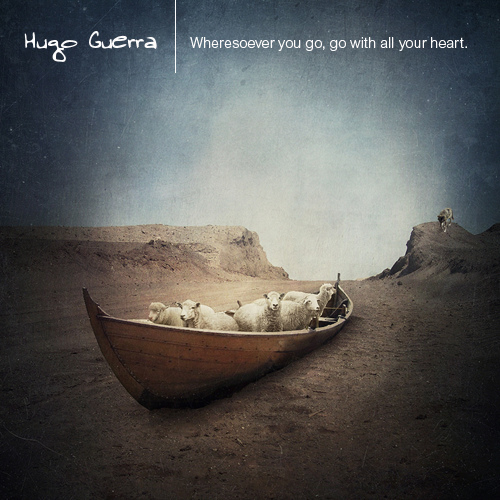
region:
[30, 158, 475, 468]
sheep contained inside boat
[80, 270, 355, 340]
curved edge of side of boat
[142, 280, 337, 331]
white sheep looking in different directions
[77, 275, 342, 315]
open far side of boat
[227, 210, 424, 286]
large opening between rocky partition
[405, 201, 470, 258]
predatory animal on flat circle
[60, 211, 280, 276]
dark and light grey ridges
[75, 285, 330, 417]
horizontal lines on boat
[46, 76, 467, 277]
muted grey and blue sky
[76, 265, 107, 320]
triangular tip of boat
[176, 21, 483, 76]
Phrase in White Font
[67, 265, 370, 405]
Wooden Planked Boat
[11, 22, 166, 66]
Name written in white cursive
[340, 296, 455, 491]
Cracked dried dirty ground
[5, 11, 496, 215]
Dark and Light Blue Sky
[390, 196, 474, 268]
Sheep with back towards cliff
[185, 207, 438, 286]
Naturally Formed Earth Depression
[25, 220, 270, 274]
Slanted Dirt Boundaries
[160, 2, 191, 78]
Short White Vertical Line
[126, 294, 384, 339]
Five White Not Sheared Sheep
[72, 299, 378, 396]
Wooden boat on land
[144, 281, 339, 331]
Five white sheep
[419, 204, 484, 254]
Man on a rock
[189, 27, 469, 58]
Wheresoever you go, go with all your heart quote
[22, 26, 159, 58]
Hugo Guerra text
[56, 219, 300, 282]
Large rock formation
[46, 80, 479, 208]
Blue skies with cloud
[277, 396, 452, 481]
Sand under the boat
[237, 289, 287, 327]
White sheep looking at the camera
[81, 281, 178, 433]
Bow of the wooden boat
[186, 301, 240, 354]
White animal in wood boat.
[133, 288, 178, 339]
White animal in wood boat.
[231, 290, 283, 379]
White animal standing in boat.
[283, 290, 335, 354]
White animal standing in boat.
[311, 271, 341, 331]
Animal standing in wood boat.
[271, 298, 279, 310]
Animal has black nose.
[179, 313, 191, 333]
Animal has black nose.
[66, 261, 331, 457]
Wood boat full of sheep sitting on dirt.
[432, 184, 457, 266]
Wolf standing in background.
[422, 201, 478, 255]
Wolf is gray in color.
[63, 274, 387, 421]
sheep in a boat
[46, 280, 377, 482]
boat on a dirt road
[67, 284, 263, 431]
bow of wooden boat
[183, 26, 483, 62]
travel related saying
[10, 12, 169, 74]
name of person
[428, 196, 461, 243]
object on rock outcrop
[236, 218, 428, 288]
pass through rise for road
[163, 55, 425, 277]
white haze in sky behind pass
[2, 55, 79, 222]
dark blue sky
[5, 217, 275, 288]
two raised rows of land